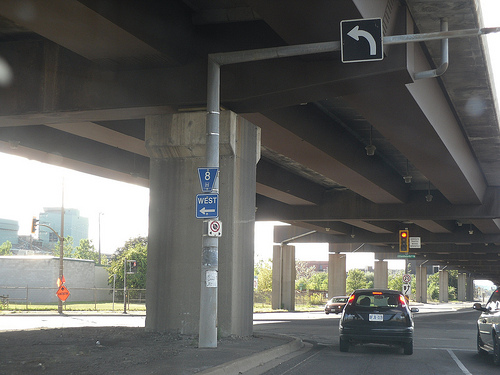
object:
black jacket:
[195, 165, 221, 220]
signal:
[399, 229, 409, 252]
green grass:
[115, 301, 144, 311]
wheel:
[339, 337, 348, 353]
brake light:
[372, 291, 382, 295]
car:
[324, 295, 350, 314]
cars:
[473, 285, 500, 368]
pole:
[195, 47, 223, 351]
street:
[1, 303, 498, 375]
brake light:
[398, 294, 406, 306]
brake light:
[347, 293, 355, 304]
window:
[354, 292, 399, 308]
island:
[0, 325, 500, 375]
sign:
[56, 283, 70, 303]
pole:
[57, 210, 64, 315]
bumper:
[341, 325, 415, 334]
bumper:
[324, 307, 339, 310]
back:
[340, 289, 416, 347]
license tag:
[369, 313, 384, 322]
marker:
[411, 346, 472, 373]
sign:
[339, 17, 388, 64]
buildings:
[36, 206, 91, 255]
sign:
[207, 217, 224, 237]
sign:
[196, 193, 218, 219]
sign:
[402, 283, 411, 297]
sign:
[409, 235, 419, 250]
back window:
[354, 291, 405, 310]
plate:
[367, 312, 385, 322]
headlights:
[327, 305, 342, 308]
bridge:
[2, 1, 500, 288]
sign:
[197, 167, 219, 192]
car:
[338, 287, 419, 356]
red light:
[400, 232, 406, 238]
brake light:
[391, 313, 407, 323]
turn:
[445, 298, 486, 309]